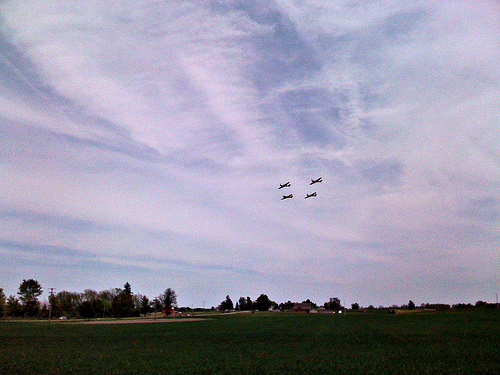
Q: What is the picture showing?
A: It is showing a field.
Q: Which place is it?
A: It is a field.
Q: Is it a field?
A: Yes, it is a field.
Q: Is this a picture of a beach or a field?
A: It is showing a field.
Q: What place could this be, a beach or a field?
A: It is a field.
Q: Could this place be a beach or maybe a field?
A: It is a field.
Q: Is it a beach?
A: No, it is a field.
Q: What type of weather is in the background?
A: It is cloudy.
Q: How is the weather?
A: It is cloudy.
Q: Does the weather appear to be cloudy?
A: Yes, it is cloudy.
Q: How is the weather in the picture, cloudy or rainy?
A: It is cloudy.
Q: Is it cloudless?
A: No, it is cloudy.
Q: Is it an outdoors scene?
A: Yes, it is outdoors.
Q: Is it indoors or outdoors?
A: It is outdoors.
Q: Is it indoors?
A: No, it is outdoors.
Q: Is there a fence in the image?
A: No, there are no fences.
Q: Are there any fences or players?
A: No, there are no fences or players.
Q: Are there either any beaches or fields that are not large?
A: No, there is a field but it is large.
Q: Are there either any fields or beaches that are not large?
A: No, there is a field but it is large.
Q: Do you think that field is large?
A: Yes, the field is large.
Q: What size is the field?
A: The field is large.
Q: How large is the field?
A: The field is large.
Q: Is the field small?
A: No, the field is large.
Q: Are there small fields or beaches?
A: No, there is a field but it is large.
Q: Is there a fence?
A: No, there are no fences.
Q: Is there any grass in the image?
A: Yes, there is grass.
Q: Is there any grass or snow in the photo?
A: Yes, there is grass.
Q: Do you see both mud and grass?
A: No, there is grass but no mud.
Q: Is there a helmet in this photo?
A: No, there are no helmets.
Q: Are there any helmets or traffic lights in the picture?
A: No, there are no helmets or traffic lights.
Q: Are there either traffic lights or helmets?
A: No, there are no helmets or traffic lights.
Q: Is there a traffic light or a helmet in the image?
A: No, there are no helmets or traffic lights.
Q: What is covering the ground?
A: The grass is covering the ground.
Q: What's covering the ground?
A: The grass is covering the ground.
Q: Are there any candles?
A: No, there are no candles.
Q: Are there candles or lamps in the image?
A: No, there are no candles or lamps.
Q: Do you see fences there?
A: No, there are no fences.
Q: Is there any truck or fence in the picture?
A: No, there are no fences or trucks.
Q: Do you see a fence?
A: No, there are no fences.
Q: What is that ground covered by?
A: The ground is covered by the grass.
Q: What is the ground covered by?
A: The ground is covered by the grass.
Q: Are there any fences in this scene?
A: No, there are no fences.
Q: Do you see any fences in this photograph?
A: No, there are no fences.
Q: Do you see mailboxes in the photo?
A: No, there are no mailboxes.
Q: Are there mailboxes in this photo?
A: No, there are no mailboxes.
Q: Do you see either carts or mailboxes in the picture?
A: No, there are no mailboxes or carts.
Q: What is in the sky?
A: The clouds are in the sky.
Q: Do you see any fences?
A: No, there are no fences.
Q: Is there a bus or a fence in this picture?
A: No, there are no fences or buses.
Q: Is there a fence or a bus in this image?
A: No, there are no fences or buses.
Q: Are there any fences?
A: No, there are no fences.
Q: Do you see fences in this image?
A: No, there are no fences.